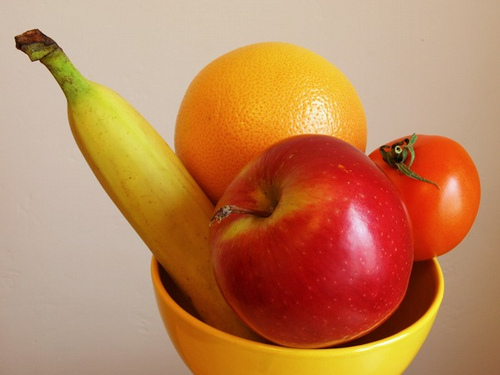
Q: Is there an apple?
A: Yes, there is an apple.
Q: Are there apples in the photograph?
A: Yes, there is an apple.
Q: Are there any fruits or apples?
A: Yes, there is an apple.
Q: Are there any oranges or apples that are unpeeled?
A: Yes, the apple is unpeeled.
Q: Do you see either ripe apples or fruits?
A: Yes, there is a ripe apple.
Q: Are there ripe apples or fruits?
A: Yes, there is a ripe apple.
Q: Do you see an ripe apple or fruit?
A: Yes, there is a ripe apple.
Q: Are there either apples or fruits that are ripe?
A: Yes, the apple is ripe.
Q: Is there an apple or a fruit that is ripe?
A: Yes, the apple is ripe.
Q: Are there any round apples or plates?
A: Yes, there is a round apple.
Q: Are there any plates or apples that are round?
A: Yes, the apple is round.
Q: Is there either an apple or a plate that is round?
A: Yes, the apple is round.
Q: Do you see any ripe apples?
A: Yes, there is a ripe apple.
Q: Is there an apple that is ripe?
A: Yes, there is an apple that is ripe.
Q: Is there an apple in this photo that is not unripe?
A: Yes, there is an ripe apple.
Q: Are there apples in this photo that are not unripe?
A: Yes, there is an ripe apple.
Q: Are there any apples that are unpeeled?
A: Yes, there is an unpeeled apple.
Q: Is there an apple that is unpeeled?
A: Yes, there is an apple that is unpeeled.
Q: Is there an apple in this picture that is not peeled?
A: Yes, there is a unpeeled apple.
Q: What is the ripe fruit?
A: The fruit is an apple.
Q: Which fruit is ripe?
A: The fruit is an apple.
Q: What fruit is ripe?
A: The fruit is an apple.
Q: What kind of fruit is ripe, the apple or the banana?
A: The apple is ripe.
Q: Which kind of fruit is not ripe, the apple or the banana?
A: The banana is not ripe.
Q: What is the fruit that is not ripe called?
A: The fruit is a banana.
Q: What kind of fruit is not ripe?
A: The fruit is a banana.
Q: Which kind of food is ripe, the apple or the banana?
A: The apple is ripe.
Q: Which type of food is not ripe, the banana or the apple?
A: The banana is not ripe.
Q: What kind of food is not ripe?
A: The food is a banana.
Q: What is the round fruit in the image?
A: The fruit is an apple.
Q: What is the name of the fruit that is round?
A: The fruit is an apple.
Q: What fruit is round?
A: The fruit is an apple.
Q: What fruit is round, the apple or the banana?
A: The apple is round.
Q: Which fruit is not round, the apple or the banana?
A: The banana is not round.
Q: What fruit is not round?
A: The fruit is a banana.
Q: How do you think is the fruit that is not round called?
A: The fruit is a banana.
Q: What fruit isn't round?
A: The fruit is a banana.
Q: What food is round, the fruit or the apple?
A: The apple is round.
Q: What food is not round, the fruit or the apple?
A: The fruit is not round.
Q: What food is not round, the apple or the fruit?
A: The fruit is not round.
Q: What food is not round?
A: The food is a fruit.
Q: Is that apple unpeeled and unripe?
A: No, the apple is unpeeled but ripe.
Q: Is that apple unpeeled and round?
A: Yes, the apple is unpeeled and round.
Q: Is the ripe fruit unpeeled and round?
A: Yes, the apple is unpeeled and round.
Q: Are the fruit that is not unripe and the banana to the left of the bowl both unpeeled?
A: Yes, both the apple and the banana are unpeeled.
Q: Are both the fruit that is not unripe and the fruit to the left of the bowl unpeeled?
A: Yes, both the apple and the banana are unpeeled.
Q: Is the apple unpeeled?
A: Yes, the apple is unpeeled.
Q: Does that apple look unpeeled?
A: Yes, the apple is unpeeled.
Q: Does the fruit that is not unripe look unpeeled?
A: Yes, the apple is unpeeled.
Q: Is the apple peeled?
A: No, the apple is unpeeled.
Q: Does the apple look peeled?
A: No, the apple is unpeeled.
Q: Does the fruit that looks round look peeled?
A: No, the apple is unpeeled.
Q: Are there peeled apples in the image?
A: No, there is an apple but it is unpeeled.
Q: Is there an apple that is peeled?
A: No, there is an apple but it is unpeeled.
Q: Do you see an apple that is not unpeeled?
A: No, there is an apple but it is unpeeled.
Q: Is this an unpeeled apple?
A: Yes, this is an unpeeled apple.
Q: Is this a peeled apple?
A: No, this is an unpeeled apple.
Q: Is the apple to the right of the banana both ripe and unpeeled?
A: Yes, the apple is ripe and unpeeled.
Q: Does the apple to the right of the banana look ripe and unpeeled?
A: Yes, the apple is ripe and unpeeled.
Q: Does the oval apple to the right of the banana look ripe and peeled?
A: No, the apple is ripe but unpeeled.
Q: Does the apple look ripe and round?
A: Yes, the apple is ripe and round.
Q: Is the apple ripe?
A: Yes, the apple is ripe.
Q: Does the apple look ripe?
A: Yes, the apple is ripe.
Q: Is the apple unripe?
A: No, the apple is ripe.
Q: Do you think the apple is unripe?
A: No, the apple is ripe.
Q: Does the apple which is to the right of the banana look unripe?
A: No, the apple is ripe.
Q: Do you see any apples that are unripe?
A: No, there is an apple but it is ripe.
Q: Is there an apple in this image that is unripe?
A: No, there is an apple but it is ripe.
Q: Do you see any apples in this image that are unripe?
A: No, there is an apple but it is ripe.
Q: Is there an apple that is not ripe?
A: No, there is an apple but it is ripe.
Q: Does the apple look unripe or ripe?
A: The apple is ripe.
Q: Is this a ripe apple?
A: Yes, this is a ripe apple.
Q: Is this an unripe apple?
A: No, this is a ripe apple.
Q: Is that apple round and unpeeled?
A: Yes, the apple is round and unpeeled.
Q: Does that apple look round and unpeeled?
A: Yes, the apple is round and unpeeled.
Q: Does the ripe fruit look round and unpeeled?
A: Yes, the apple is round and unpeeled.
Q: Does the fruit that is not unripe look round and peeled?
A: No, the apple is round but unpeeled.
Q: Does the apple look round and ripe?
A: Yes, the apple is round and ripe.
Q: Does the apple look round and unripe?
A: No, the apple is round but ripe.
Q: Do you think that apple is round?
A: Yes, the apple is round.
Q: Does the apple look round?
A: Yes, the apple is round.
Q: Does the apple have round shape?
A: Yes, the apple is round.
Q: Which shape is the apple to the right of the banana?
A: The apple is round.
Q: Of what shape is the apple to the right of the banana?
A: The apple is round.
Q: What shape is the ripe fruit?
A: The apple is round.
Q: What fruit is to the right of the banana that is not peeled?
A: The fruit is an apple.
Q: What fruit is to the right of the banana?
A: The fruit is an apple.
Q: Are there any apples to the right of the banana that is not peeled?
A: Yes, there is an apple to the right of the banana.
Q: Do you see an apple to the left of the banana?
A: No, the apple is to the right of the banana.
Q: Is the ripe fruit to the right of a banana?
A: Yes, the apple is to the right of a banana.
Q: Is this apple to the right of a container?
A: No, the apple is to the right of a banana.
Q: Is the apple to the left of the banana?
A: No, the apple is to the right of the banana.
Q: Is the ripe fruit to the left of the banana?
A: No, the apple is to the right of the banana.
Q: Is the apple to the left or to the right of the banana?
A: The apple is to the right of the banana.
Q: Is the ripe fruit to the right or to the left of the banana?
A: The apple is to the right of the banana.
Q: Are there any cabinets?
A: No, there are no cabinets.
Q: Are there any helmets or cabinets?
A: No, there are no cabinets or helmets.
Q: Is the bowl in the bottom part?
A: Yes, the bowl is in the bottom of the image.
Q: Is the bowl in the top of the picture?
A: No, the bowl is in the bottom of the image.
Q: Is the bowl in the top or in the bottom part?
A: The bowl is in the bottom of the image.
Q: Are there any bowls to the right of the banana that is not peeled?
A: Yes, there is a bowl to the right of the banana.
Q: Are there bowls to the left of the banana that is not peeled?
A: No, the bowl is to the right of the banana.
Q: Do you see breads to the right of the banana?
A: No, there is a bowl to the right of the banana.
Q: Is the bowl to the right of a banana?
A: Yes, the bowl is to the right of a banana.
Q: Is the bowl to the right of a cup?
A: No, the bowl is to the right of a banana.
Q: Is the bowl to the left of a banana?
A: No, the bowl is to the right of a banana.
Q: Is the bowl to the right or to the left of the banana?
A: The bowl is to the right of the banana.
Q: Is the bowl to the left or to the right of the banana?
A: The bowl is to the right of the banana.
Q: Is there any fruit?
A: Yes, there is a fruit.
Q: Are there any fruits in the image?
A: Yes, there is a fruit.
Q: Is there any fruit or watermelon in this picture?
A: Yes, there is a fruit.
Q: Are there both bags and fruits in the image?
A: No, there is a fruit but no bags.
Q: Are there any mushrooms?
A: No, there are no mushrooms.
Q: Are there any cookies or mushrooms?
A: No, there are no mushrooms or cookies.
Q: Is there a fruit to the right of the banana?
A: Yes, there is a fruit to the right of the banana.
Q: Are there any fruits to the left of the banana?
A: No, the fruit is to the right of the banana.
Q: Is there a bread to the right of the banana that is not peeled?
A: No, there is a fruit to the right of the banana.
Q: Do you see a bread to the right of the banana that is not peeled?
A: No, there is a fruit to the right of the banana.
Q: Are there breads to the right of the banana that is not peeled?
A: No, there is a fruit to the right of the banana.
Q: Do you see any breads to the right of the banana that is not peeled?
A: No, there is a fruit to the right of the banana.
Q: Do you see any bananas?
A: Yes, there is a banana.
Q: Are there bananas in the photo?
A: Yes, there is a banana.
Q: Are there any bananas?
A: Yes, there is a banana.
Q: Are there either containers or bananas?
A: Yes, there is a banana.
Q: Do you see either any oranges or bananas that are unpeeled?
A: Yes, the banana is unpeeled.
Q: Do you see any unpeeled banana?
A: Yes, there is an unpeeled banana.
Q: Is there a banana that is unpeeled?
A: Yes, there is an unpeeled banana.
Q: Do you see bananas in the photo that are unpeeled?
A: Yes, there is a banana that is unpeeled.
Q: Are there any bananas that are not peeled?
A: Yes, there is a unpeeled banana.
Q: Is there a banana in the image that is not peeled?
A: Yes, there is a unpeeled banana.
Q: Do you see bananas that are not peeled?
A: Yes, there is a unpeeled banana.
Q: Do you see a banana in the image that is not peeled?
A: Yes, there is a unpeeled banana.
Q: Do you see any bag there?
A: No, there are no bags.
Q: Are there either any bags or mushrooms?
A: No, there are no bags or mushrooms.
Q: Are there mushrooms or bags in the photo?
A: No, there are no bags or mushrooms.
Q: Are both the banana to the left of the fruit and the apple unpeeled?
A: Yes, both the banana and the apple are unpeeled.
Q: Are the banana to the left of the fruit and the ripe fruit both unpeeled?
A: Yes, both the banana and the apple are unpeeled.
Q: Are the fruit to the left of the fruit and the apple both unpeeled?
A: Yes, both the banana and the apple are unpeeled.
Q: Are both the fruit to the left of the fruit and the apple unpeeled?
A: Yes, both the banana and the apple are unpeeled.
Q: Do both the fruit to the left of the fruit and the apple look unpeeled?
A: Yes, both the banana and the apple are unpeeled.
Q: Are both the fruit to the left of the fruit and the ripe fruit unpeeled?
A: Yes, both the banana and the apple are unpeeled.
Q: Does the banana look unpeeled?
A: Yes, the banana is unpeeled.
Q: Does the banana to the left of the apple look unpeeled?
A: Yes, the banana is unpeeled.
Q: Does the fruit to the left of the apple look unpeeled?
A: Yes, the banana is unpeeled.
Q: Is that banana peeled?
A: No, the banana is unpeeled.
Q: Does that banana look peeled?
A: No, the banana is unpeeled.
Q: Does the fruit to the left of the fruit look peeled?
A: No, the banana is unpeeled.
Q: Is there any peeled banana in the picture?
A: No, there is a banana but it is unpeeled.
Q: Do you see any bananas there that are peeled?
A: No, there is a banana but it is unpeeled.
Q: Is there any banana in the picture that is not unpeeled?
A: No, there is a banana but it is unpeeled.